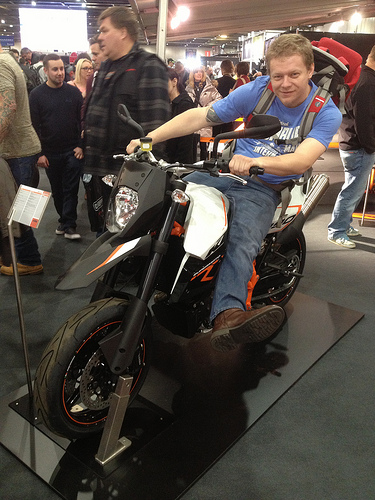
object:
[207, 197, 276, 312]
leg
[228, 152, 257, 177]
hand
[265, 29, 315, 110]
head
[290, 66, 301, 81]
eye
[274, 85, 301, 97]
mouth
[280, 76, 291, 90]
nose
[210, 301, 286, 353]
shoe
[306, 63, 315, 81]
ear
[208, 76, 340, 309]
wearing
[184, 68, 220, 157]
wearing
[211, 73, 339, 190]
shirt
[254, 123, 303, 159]
print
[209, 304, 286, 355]
left shoe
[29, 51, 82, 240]
man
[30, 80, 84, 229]
outfit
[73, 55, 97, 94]
wearing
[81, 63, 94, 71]
eyeglasses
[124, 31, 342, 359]
boy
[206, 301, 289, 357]
boot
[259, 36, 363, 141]
backpack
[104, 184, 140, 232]
headlight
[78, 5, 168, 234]
man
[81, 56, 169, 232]
shirt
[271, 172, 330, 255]
tail pipe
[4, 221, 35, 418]
pole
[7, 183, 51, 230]
sign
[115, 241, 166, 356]
frame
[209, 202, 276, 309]
jeans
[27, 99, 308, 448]
bike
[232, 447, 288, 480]
floor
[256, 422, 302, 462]
floor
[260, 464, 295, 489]
floor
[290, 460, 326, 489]
floor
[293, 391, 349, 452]
floor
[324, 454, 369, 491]
floor